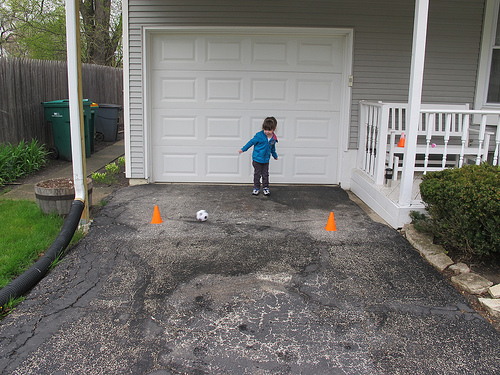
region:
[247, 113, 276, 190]
small boy in front of garage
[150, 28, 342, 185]
white garage door behind boy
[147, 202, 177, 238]
small orange cone in driveway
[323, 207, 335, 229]
small orange cone in driveway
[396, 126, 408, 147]
small orange cone on bench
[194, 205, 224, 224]
small soccer ball on driveway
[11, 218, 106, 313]
large black pipe on left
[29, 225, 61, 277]
grass growing by drive way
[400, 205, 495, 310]
stones on right of drive way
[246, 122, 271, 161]
blue jacket on boy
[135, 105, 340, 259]
a young girl playing soccer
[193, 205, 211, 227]
a small soccer ball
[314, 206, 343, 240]
a small orange pylon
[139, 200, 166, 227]
a small orange pylon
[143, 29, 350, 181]
a white garage door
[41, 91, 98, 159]
a large green trashcan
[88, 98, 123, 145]
a large gray trashcan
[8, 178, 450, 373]
an asphalt driveway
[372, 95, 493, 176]
a white bench on a porch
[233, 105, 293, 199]
a girl wearing a blue jacket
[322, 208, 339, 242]
the cone is orange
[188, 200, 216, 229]
the ball is round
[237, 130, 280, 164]
the jacket is blue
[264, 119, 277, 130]
the hair is brown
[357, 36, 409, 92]
the house is gray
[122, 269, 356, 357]
the driveway is black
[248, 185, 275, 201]
the girl is wearing shoes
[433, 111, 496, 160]
the handrail is white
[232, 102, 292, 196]
the girl is playing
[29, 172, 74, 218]
the planter is huge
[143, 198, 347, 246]
Two small orange cones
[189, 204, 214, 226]
Black and white soccer ball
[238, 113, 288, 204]
Little girl looking at the soccer ball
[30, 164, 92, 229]
Brown circle flower planter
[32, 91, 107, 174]
Two green recycle bins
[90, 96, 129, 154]
One gray trash bin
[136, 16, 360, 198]
White garage on gray house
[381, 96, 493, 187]
Pretty white bench on porch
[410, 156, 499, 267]
Small green bush in front of house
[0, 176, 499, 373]
long gray driveway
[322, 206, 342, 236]
small orange cone on the driveway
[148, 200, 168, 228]
small orange cone on the driveway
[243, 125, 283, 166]
blue jacket on a child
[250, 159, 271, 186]
grey pants on a child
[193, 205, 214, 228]
small soccer ball on the driveway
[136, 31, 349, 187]
white garage door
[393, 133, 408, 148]
small orange cone on a bench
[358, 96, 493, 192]
wooden railing on a porch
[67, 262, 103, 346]
cracked asphalt on the driveway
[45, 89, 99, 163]
green trashcans beside the garage